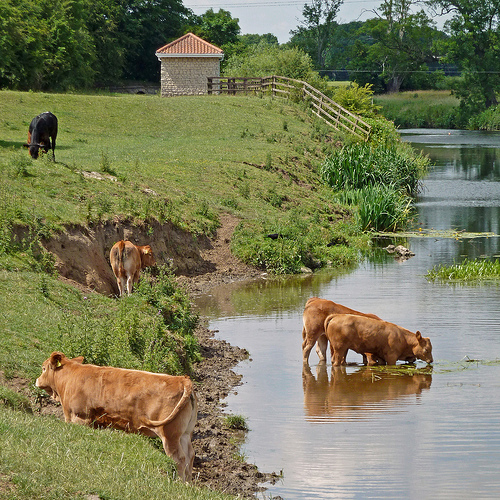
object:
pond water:
[318, 403, 386, 456]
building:
[154, 33, 223, 96]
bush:
[347, 193, 394, 230]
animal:
[22, 110, 58, 165]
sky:
[245, 10, 285, 23]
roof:
[156, 33, 223, 58]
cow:
[34, 352, 197, 483]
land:
[12, 191, 290, 493]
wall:
[160, 59, 219, 94]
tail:
[138, 379, 193, 427]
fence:
[206, 76, 371, 143]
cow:
[108, 240, 156, 297]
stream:
[193, 128, 500, 497]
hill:
[122, 93, 304, 245]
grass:
[424, 256, 499, 287]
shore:
[222, 52, 318, 271]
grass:
[0, 91, 365, 500]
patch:
[10, 302, 39, 325]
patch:
[174, 138, 198, 164]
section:
[31, 90, 230, 251]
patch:
[68, 99, 102, 119]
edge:
[218, 82, 421, 272]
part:
[426, 273, 436, 283]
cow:
[323, 313, 433, 367]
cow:
[300, 299, 386, 366]